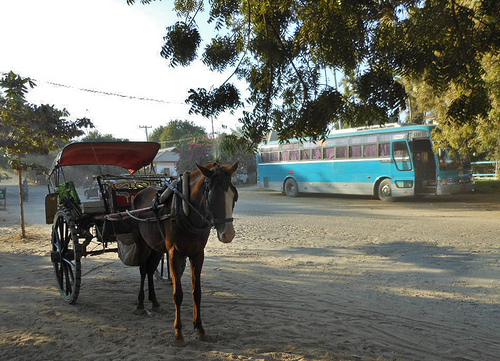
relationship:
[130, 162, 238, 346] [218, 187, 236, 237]
horse has white fur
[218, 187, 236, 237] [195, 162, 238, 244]
white fur on face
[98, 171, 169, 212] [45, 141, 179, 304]
seat of cart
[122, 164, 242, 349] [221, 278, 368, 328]
horse left foot prints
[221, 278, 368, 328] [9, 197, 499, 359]
foot prints in sand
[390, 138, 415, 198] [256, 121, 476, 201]
door on bus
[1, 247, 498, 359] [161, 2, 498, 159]
shadow of tree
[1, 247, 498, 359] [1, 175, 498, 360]
shadow on ground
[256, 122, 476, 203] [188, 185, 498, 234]
bus on side of road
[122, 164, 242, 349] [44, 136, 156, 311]
horse pulling cart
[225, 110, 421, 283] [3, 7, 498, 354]
photo of a rural area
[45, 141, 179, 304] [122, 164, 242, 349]
cart attatched to horse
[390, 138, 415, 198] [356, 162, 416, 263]
door door open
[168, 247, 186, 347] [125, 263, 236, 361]
horse legs horse has front legs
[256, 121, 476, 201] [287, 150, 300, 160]
bus has window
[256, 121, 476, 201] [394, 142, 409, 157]
bus has window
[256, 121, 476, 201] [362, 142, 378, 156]
bus has window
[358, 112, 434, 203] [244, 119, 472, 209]
boarding door open on bus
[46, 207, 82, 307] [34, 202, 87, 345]
wheel of a buggy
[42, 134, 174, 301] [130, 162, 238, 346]
cart or buggy to be pulled by a horse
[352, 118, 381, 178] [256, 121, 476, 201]
side windows of a bus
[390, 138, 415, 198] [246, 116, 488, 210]
door on bus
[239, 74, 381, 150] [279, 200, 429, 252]
branches over road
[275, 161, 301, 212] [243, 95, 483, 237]
wheel of bus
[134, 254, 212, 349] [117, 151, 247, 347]
legs of horse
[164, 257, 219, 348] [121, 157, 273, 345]
legs on horse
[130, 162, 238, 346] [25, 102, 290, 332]
horse pulling carriage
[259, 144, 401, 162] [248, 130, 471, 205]
windows on bus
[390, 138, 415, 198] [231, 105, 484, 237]
door on bus